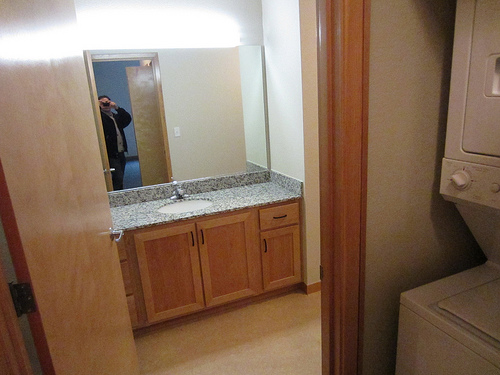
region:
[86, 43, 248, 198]
A bathroom mirror in a bathroom.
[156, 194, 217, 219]
a white sink in a bathroom.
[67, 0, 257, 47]
a bright bathroom light.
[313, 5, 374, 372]
a wooden door frame.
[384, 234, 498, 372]
a stackable washing machine.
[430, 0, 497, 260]
a stackable dryer.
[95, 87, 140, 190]
A man standing in front of a mirror.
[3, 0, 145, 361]
A wooden bathroom door.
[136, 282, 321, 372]
a bathroom floor.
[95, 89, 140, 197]
a person taking a selfie.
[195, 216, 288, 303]
these are the drawers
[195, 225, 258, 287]
the drawers are closed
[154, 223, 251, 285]
the drawers are wooden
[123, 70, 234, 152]
this is a mirror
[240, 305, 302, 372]
this is the floor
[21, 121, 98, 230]
this is the door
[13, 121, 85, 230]
the door is wooden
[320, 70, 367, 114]
this is the frame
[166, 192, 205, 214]
this is the sink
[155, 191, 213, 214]
the sink is clean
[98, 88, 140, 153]
this is a man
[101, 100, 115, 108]
the man is light skinned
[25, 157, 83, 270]
this is a door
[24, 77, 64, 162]
the door is wooden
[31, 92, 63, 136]
the door is open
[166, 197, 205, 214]
this is a sink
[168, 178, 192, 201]
this is a tap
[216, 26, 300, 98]
this is the wall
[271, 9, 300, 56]
the wall is white in color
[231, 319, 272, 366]
this is the floor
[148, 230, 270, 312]
these are the drawers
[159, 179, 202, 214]
this is a sink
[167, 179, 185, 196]
this is a tap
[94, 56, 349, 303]
this is the door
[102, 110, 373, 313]
the door is open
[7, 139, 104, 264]
the door is wooden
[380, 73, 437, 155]
this is the wall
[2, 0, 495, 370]
Bathroom with door opened.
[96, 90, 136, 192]
Photographer seen on the mirror.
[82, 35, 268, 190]
Bathroom with large mirror.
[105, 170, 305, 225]
Bathroom-countertop made of granite.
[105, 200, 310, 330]
Bathroom cabinets made of light wood.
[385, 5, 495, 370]
Stackable washer and dryer in a room corner.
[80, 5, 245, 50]
Bright light on top of the large mirror.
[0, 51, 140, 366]
Bathroom door made of wood.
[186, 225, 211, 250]
Cabinets with black metal handles.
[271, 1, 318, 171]
White painted wall.